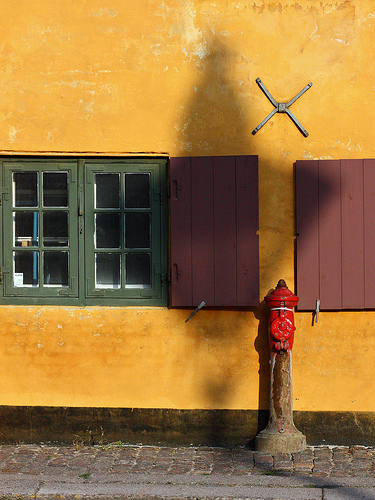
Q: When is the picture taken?
A: Day time.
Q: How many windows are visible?
A: Two.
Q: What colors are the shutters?
A: Brown.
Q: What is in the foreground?
A: Curb and stone sidewalk.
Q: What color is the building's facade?
A: A shade of orange.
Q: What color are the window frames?
A: Green.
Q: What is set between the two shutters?
A: A stone pole with a red top.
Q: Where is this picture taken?
A: Street.